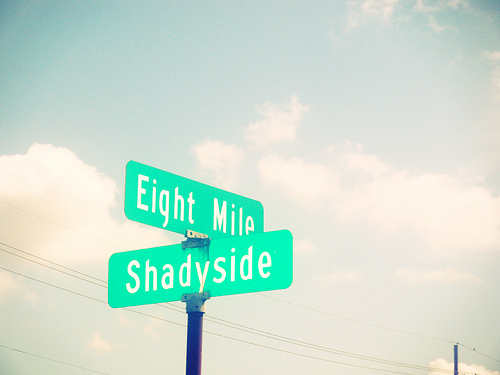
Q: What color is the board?
A: Green.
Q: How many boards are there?
A: 2.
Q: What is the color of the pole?
A: Blue.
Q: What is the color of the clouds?
A: White.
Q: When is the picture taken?
A: Daytime.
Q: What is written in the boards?
A: Eight mile and shadyside.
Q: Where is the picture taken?
A: At the intersection of Eight Mile and Shadyside.